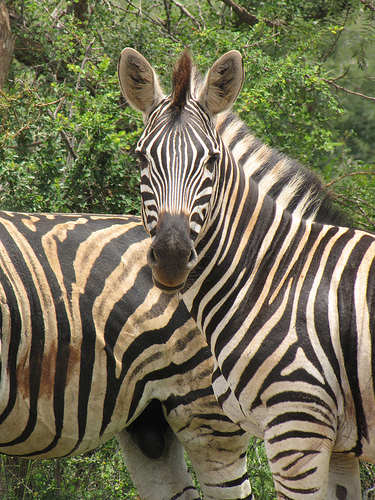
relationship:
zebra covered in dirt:
[0, 164, 348, 497] [1, 320, 114, 401]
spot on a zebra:
[5, 262, 56, 338] [1, 206, 255, 498]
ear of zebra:
[115, 44, 166, 116] [114, 43, 362, 498]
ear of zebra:
[193, 47, 247, 113] [114, 43, 362, 498]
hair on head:
[171, 47, 194, 109] [116, 42, 246, 294]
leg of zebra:
[261, 390, 342, 498] [114, 43, 362, 498]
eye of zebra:
[205, 151, 221, 167] [114, 43, 362, 498]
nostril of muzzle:
[147, 245, 157, 265] [145, 228, 197, 296]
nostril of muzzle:
[184, 242, 201, 269] [145, 228, 197, 296]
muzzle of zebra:
[145, 228, 197, 296] [114, 43, 362, 498]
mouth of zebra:
[149, 274, 189, 297] [114, 43, 362, 498]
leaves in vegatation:
[35, 99, 90, 171] [0, 0, 375, 228]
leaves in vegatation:
[2, 82, 50, 136] [0, 0, 375, 228]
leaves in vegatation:
[301, 21, 346, 51] [0, 0, 375, 228]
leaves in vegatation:
[281, 115, 338, 160] [0, 0, 375, 228]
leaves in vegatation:
[0, 69, 51, 116] [0, 0, 375, 228]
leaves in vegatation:
[26, 87, 74, 144] [0, 0, 375, 228]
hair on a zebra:
[171, 47, 194, 109] [114, 43, 362, 498]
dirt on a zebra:
[11, 337, 84, 401] [2, 202, 273, 487]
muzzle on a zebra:
[145, 228, 197, 296] [101, 40, 374, 434]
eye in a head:
[128, 143, 165, 185] [116, 44, 245, 297]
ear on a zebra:
[198, 48, 246, 115] [107, 39, 354, 375]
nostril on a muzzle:
[145, 243, 159, 267] [145, 228, 197, 296]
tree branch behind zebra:
[223, 2, 280, 38] [101, 40, 374, 434]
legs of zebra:
[236, 398, 344, 498] [114, 43, 362, 498]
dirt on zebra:
[11, 337, 84, 401] [3, 182, 288, 498]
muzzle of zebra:
[142, 213, 198, 300] [114, 43, 362, 498]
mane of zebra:
[170, 39, 335, 227] [114, 43, 362, 498]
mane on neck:
[170, 39, 335, 227] [174, 146, 302, 364]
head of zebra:
[106, 34, 363, 494] [106, 41, 255, 302]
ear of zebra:
[198, 48, 246, 115] [114, 43, 362, 498]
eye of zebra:
[202, 148, 221, 171] [114, 43, 362, 498]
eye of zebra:
[136, 148, 150, 171] [114, 43, 362, 498]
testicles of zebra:
[126, 402, 175, 464] [2, 202, 273, 487]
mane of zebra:
[215, 111, 351, 227] [114, 43, 362, 498]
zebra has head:
[114, 43, 362, 498] [107, 44, 265, 307]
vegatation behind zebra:
[3, 3, 362, 236] [114, 43, 362, 498]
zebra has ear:
[114, 43, 362, 498] [194, 47, 251, 122]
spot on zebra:
[5, 338, 87, 400] [2, 202, 273, 487]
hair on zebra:
[171, 47, 194, 109] [114, 43, 362, 498]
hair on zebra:
[182, 57, 352, 230] [114, 43, 362, 498]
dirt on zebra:
[11, 337, 84, 401] [1, 206, 255, 498]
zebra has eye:
[114, 43, 362, 498] [205, 151, 222, 165]